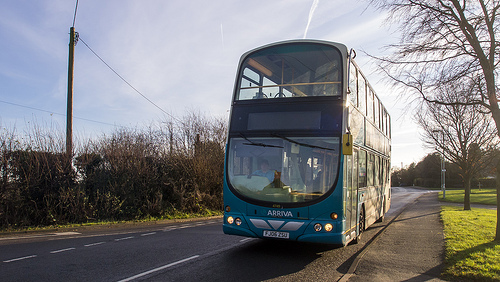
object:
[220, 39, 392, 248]
bus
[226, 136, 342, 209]
window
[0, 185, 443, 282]
road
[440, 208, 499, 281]
grass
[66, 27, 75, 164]
pole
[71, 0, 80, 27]
wire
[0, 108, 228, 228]
bushes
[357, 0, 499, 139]
tree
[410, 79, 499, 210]
tree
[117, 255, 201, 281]
line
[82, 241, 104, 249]
line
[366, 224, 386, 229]
shadow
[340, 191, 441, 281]
sidewalk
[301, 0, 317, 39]
line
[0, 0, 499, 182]
sky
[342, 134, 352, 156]
mirror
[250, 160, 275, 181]
man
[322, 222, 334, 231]
light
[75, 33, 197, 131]
line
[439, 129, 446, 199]
street light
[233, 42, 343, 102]
window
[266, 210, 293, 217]
arriva